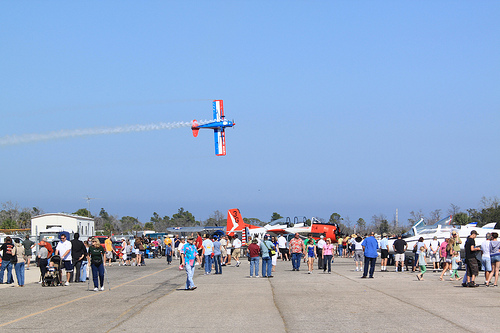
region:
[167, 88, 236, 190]
red white and blue plane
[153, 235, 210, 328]
blue and pink shirt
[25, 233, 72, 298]
man pushing a stroller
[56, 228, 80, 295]
man in white shirt and blue shorts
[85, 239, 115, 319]
woman wearing a fanny pack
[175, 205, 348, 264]
orange and white plane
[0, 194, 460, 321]
people at an air show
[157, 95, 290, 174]
aiur plane in the sky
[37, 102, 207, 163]
trail of smoke behind a plane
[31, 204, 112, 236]
white air plane hangar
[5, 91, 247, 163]
airplane in sky leaving a white smoke trail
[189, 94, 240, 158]
red, white, and blue airplane flying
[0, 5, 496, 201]
airplane flying in blue skies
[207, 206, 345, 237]
red plane out in distance on airport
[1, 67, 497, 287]
a group of people watching an airshow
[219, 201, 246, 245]
tail of a red and white plane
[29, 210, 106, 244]
white mobile home in the background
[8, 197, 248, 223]
many green trees in distance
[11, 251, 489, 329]
cemented airport where people are standing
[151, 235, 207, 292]
person wearing a blue shirt and jeans walking on cement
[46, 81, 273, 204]
the airplane is flying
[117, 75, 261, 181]
the airplane is red white and blue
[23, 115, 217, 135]
the smoke trail behind the airplane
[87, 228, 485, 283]
a crowd of people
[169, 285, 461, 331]
the ground is paved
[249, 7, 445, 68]
the sky is blue and clear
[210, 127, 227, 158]
the wing of the airplane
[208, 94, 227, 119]
the wing of the airplane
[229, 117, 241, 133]
the propeller of the airplane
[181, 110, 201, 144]
the tail of the airplane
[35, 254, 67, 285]
small child being pushed in stroller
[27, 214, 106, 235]
manufactured mobile housing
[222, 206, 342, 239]
orange and white plane with open cockpit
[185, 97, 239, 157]
red, white and blue plane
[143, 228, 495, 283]
crowd of people at air show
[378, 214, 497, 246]
part of white plane parked on side of airstrip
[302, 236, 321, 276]
young woman in shorts and sleeveless shirt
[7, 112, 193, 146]
exhaust from plane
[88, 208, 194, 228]
trees standing around border of airstrip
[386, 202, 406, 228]
tower or monument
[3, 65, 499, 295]
an airshow with a large crowd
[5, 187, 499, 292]
people at the fair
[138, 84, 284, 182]
an airplane doing stunts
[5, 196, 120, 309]
a white bus in the crowd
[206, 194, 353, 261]
red and white plane by the spectators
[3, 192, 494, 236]
trees along the line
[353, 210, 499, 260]
a white plane by the people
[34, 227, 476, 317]
the fair is on a runway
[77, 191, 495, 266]
the crowd enjoys the plane show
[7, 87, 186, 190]
this plane is leaving a trail of smoke